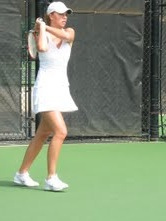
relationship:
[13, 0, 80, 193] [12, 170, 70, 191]
girl in shoes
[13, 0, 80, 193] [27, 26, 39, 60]
girl has racquet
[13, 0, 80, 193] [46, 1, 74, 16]
girl wearing cap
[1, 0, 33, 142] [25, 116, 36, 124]
gate has hinge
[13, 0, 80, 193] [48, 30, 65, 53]
girl has v-neck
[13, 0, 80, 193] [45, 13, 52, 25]
girl has hair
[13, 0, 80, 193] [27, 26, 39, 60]
girl holds racquet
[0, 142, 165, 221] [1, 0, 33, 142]
court has gate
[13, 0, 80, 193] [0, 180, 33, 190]
girl has shadow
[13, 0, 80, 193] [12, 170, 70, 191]
girl has shoes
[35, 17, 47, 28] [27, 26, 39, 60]
hand on racquet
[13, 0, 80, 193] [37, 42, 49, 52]
girl has elbow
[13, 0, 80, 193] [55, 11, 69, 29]
girl has face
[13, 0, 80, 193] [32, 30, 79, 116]
girl has dress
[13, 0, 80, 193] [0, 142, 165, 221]
girl on court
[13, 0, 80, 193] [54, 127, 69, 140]
girl has knee